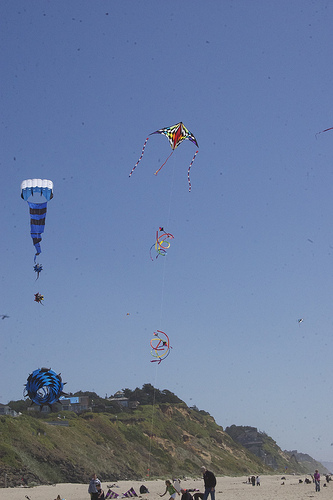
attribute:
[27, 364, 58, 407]
kite — blue, black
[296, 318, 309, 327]
airplane — Blue, white, striped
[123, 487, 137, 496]
kite — purple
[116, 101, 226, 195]
airplane — Blue, white, striped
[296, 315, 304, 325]
airplane — striped, Blue, white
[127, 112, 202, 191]
kite — multi-colored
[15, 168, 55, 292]
blue kite — white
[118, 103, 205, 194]
kite — black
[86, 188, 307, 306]
sky — clear, blue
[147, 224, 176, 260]
kite — big, colorful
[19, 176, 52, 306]
kite — big, colorful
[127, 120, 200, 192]
kite — big, colorful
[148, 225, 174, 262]
kite — multi-color, spiral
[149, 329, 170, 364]
kite — multi-color, spiral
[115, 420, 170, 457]
grassy — rocky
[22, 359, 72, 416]
kite — huge, blue, black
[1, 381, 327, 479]
hill — grassy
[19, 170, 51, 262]
airplane — blue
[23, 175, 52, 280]
airplane — striped, blue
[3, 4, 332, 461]
sky — white, striped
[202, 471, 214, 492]
shirt — black